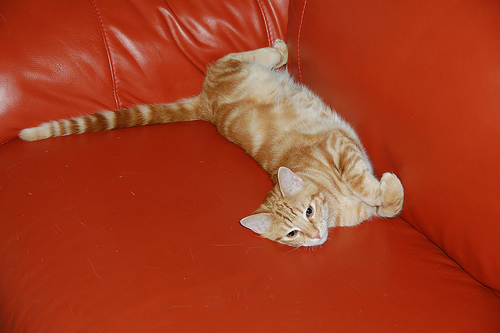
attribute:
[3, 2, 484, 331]
sofa — red, leather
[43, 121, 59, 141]
stripe — orange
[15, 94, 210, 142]
tail — cat's, striped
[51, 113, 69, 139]
stripe — orange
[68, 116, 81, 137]
stripe — orange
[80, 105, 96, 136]
stripe — orange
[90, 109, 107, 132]
stripe — orange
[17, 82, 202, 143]
tail — cat's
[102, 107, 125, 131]
stripe — orange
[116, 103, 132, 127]
stripe — orange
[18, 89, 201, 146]
tail — cat's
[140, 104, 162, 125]
stripe — orange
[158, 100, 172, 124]
stripe — orange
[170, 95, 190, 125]
stripe — orange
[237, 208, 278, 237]
ear — cat's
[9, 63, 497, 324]
couch — red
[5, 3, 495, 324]
cat — orange, white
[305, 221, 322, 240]
nose — cat's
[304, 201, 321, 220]
eye — cat's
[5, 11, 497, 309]
couch — orange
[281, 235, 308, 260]
whiskers — white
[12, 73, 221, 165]
tail — long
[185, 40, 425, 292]
cat — tabby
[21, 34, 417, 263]
kitten — tan, white, striped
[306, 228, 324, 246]
nose — pink